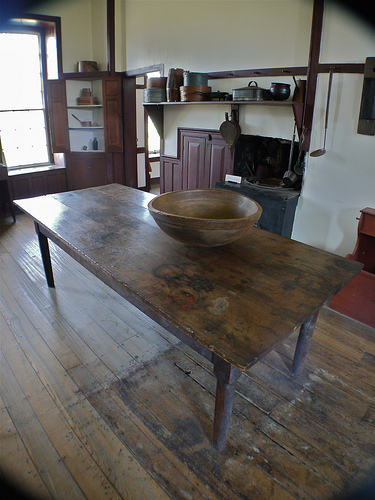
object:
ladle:
[306, 68, 334, 160]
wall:
[91, 2, 375, 258]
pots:
[181, 70, 208, 88]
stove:
[211, 132, 304, 239]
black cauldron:
[268, 82, 291, 102]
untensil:
[305, 64, 340, 161]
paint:
[180, 295, 195, 313]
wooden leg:
[34, 218, 55, 292]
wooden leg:
[289, 309, 317, 378]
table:
[11, 182, 365, 451]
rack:
[187, 62, 364, 80]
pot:
[77, 60, 97, 73]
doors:
[101, 71, 124, 152]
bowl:
[145, 186, 263, 250]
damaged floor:
[89, 302, 374, 497]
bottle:
[92, 136, 98, 151]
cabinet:
[42, 71, 124, 191]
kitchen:
[0, 2, 373, 497]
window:
[0, 108, 51, 170]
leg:
[210, 378, 237, 452]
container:
[230, 78, 271, 103]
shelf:
[143, 98, 295, 110]